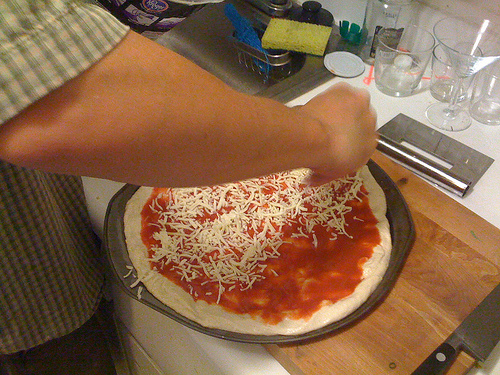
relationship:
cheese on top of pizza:
[138, 160, 362, 285] [118, 160, 388, 329]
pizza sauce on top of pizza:
[143, 185, 380, 323] [118, 160, 388, 329]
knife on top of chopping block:
[412, 278, 499, 373] [274, 145, 499, 371]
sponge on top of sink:
[260, 16, 329, 58] [143, 17, 336, 103]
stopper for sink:
[103, 0, 184, 32] [76, 4, 333, 211]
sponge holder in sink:
[241, 3, 298, 70] [63, 0, 355, 244]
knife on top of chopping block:
[410, 284, 499, 374] [287, 149, 498, 375]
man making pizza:
[24, 25, 356, 234] [148, 166, 371, 313]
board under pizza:
[364, 157, 499, 344] [112, 166, 399, 341]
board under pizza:
[261, 146, 498, 374] [112, 166, 399, 341]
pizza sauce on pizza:
[140, 175, 380, 328] [118, 160, 388, 329]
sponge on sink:
[258, 15, 334, 57] [154, 1, 379, 105]